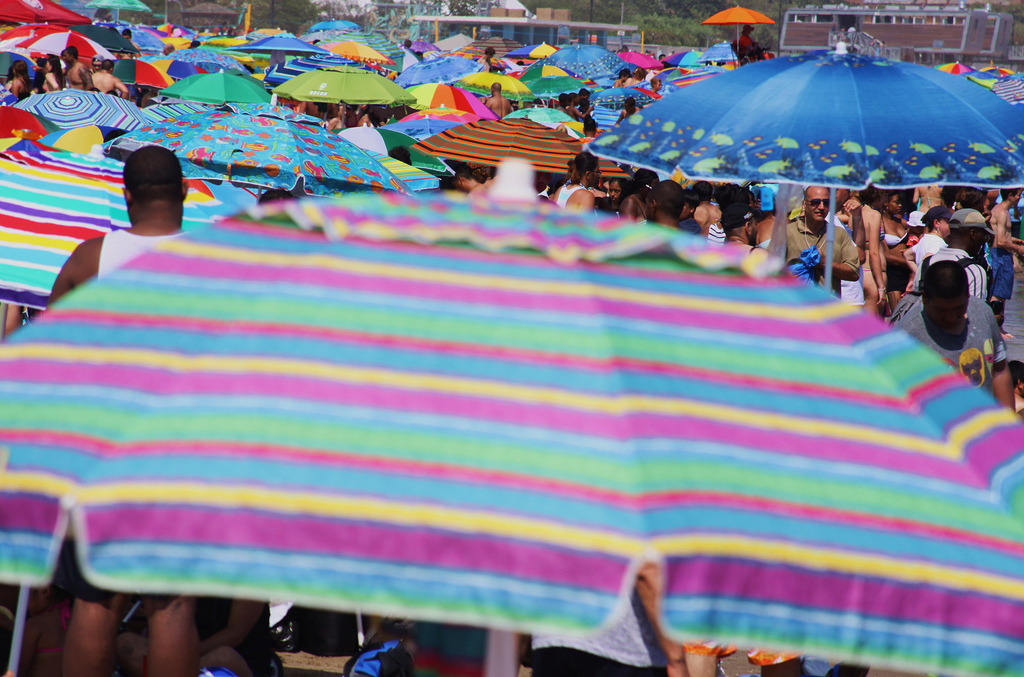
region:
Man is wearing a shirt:
[96, 217, 195, 281]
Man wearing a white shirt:
[83, 215, 197, 289]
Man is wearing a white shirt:
[90, 219, 185, 284]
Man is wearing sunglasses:
[803, 184, 836, 214]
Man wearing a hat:
[937, 201, 1004, 246]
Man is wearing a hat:
[934, 197, 1004, 240]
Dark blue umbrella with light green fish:
[587, 46, 1021, 297]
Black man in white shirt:
[38, 143, 210, 675]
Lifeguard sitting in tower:
[697, 7, 780, 65]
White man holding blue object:
[780, 182, 861, 291]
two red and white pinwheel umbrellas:
[0, 21, 118, 66]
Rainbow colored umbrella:
[400, 77, 505, 122]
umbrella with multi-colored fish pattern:
[103, 106, 423, 199]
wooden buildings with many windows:
[777, 4, 1015, 61]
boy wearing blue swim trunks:
[988, 185, 1021, 341]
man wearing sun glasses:
[782, 177, 862, 294]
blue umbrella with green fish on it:
[589, 37, 1022, 196]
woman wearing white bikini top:
[868, 187, 913, 314]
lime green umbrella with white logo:
[261, 60, 418, 111]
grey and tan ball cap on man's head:
[940, 206, 995, 239]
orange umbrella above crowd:
[702, 2, 772, 73]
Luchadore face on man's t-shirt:
[953, 342, 989, 388]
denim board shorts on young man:
[988, 228, 1015, 306]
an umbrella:
[183, 230, 787, 610]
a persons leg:
[148, 606, 188, 670]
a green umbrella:
[293, 66, 396, 112]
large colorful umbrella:
[4, 187, 1022, 655]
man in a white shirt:
[46, 145, 193, 311]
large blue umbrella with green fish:
[580, 44, 1018, 209]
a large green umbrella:
[282, 66, 415, 115]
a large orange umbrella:
[696, 3, 776, 61]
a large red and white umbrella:
[7, 21, 121, 70]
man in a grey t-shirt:
[896, 253, 1013, 408]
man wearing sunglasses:
[776, 183, 862, 301]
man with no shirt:
[980, 189, 1019, 323]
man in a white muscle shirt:
[545, 149, 606, 214]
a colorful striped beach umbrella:
[3, 184, 1018, 671]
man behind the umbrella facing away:
[42, 143, 202, 674]